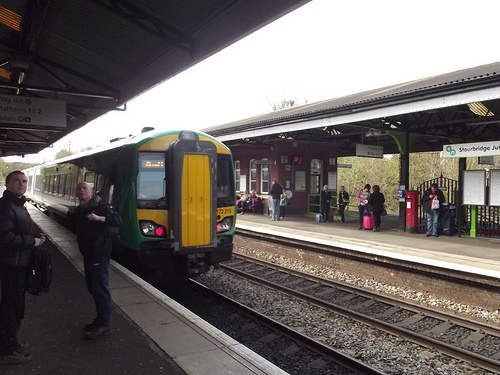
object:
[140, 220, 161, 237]
light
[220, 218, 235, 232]
light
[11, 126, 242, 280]
train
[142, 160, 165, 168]
destination sign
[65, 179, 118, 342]
man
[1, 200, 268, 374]
platform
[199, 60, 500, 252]
shelter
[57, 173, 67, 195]
windows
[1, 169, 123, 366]
two men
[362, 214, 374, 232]
suitcase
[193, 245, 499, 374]
ballast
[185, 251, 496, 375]
railway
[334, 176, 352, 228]
people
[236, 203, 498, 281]
platform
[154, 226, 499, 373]
tracks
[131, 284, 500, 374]
set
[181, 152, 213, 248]
color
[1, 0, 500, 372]
station